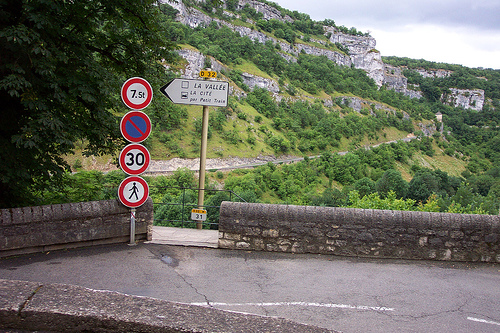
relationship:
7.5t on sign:
[128, 80, 149, 102] [124, 75, 153, 106]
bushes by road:
[227, 104, 341, 140] [208, 134, 341, 168]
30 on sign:
[122, 150, 144, 167] [122, 143, 157, 173]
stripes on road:
[211, 286, 321, 327] [144, 246, 358, 329]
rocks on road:
[215, 140, 244, 167] [208, 134, 341, 168]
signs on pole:
[120, 175, 149, 206] [123, 204, 148, 241]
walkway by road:
[156, 215, 217, 247] [208, 134, 341, 168]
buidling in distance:
[422, 92, 451, 136] [7, 17, 497, 142]